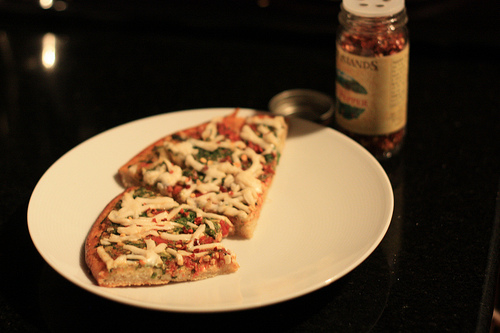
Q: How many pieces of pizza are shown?
A: Two.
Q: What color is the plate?
A: White.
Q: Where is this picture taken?
A: A kitchen.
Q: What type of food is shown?
A: Pizza.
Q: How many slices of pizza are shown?
A: Two.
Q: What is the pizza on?
A: Plate.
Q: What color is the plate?
A: White.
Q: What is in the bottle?
A: Red pepper flakes.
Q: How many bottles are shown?
A: One.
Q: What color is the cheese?
A: White.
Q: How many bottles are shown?
A: One.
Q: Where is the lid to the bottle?
A: Beside the bottle.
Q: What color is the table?
A: Black.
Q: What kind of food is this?
A: Pizza.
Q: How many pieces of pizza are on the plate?
A: Two.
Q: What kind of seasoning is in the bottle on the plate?
A: Red pepper flakes.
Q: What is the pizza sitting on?
A: Plate.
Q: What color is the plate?
A: White plate.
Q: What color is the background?
A: Black.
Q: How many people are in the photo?
A: None.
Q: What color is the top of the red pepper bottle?
A: White.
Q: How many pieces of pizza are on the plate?
A: Two.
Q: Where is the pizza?
A: On the plate.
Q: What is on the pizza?
A: Cheese.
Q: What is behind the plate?
A: Red pepper.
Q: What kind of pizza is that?
A: Cheese.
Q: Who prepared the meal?
A: A chef.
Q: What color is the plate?
A: White.